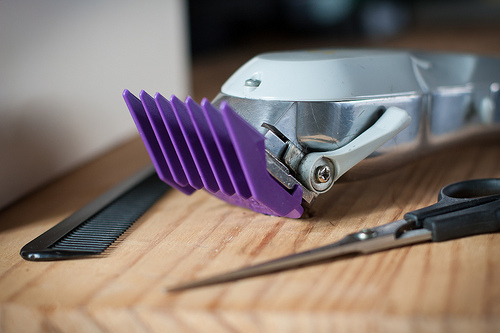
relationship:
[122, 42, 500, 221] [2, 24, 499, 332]
razor machine on top of table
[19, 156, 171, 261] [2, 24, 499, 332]
comb on top of table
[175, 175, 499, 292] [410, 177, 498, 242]
scissors have handle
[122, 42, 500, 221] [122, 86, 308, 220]
razor machine has blade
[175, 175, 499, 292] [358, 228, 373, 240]
scissors have screw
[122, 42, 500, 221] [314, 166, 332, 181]
razor machine has screw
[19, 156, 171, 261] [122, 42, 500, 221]
comb next to razor machine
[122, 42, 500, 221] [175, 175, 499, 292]
razor machine next to scissors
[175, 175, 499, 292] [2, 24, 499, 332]
scissors on top of table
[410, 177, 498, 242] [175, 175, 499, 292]
handle on top of scissors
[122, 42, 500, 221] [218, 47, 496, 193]
razor machine has section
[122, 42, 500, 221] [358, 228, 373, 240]
razor machine has screw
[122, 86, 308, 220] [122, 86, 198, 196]
blade has part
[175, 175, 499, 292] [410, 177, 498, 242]
scissors has handle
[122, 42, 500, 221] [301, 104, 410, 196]
razor machine has level